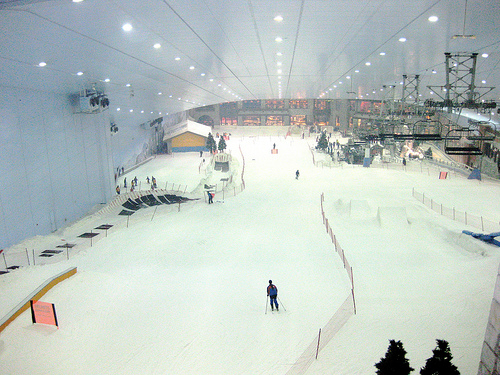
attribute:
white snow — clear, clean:
[123, 256, 227, 368]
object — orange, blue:
[437, 167, 449, 181]